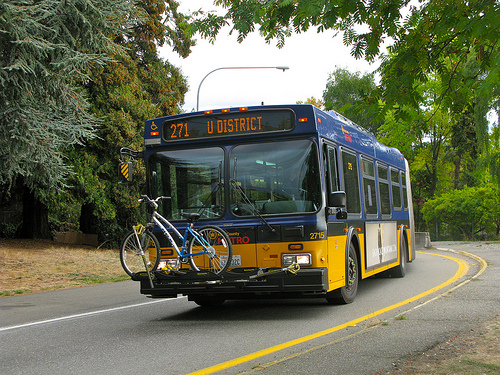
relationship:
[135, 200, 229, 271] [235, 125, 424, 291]
bike on bus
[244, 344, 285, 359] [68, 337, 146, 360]
lines on road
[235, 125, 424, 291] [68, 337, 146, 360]
bus on road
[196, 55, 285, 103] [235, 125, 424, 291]
street light above bus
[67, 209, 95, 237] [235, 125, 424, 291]
tree beside bus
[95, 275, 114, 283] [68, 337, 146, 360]
grass beside road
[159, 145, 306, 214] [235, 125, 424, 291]
windshield of bus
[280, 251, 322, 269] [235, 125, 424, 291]
head light of bus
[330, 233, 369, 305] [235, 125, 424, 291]
tire of bus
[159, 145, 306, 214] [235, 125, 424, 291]
windshield on bus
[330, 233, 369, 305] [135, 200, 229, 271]
tire on bike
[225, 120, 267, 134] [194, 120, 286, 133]
words on sign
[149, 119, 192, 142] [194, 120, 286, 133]
number on sign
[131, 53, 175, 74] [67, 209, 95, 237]
leaves on tree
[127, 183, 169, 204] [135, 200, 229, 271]
handlebars on bike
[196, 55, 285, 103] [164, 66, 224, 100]
street light on pole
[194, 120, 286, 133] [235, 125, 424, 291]
sign on bus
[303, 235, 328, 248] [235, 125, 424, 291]
symbol on bus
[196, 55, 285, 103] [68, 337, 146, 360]
street light over road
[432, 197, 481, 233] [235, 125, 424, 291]
bushes behind bus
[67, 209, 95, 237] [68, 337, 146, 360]
tree on road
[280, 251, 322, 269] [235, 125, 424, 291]
head light on bus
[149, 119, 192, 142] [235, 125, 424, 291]
number on bus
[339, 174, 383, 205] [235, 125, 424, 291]
window on bus